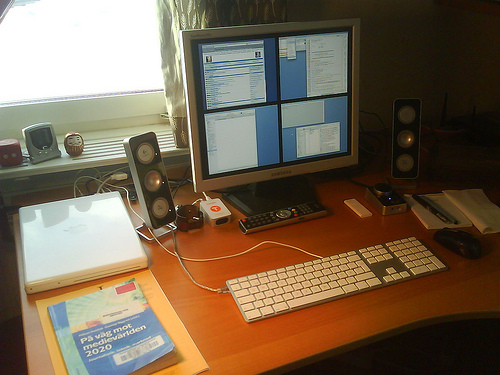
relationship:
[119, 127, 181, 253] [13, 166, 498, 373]
speaker on a desk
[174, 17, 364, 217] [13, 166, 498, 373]
computer on a desk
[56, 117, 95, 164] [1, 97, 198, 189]
figuren on cile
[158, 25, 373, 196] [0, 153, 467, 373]
computer on desk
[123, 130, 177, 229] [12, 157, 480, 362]
speaker on table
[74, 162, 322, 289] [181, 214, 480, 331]
wires from keyboard